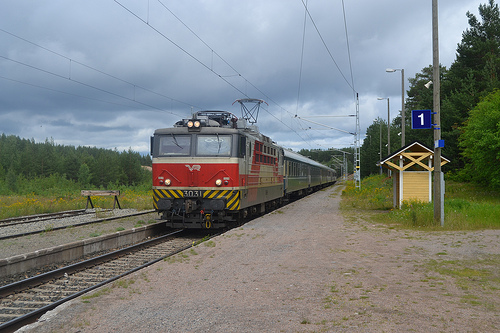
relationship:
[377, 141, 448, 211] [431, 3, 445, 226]
structure on light post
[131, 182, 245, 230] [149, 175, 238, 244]
panel on engine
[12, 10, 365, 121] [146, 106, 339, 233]
wires above train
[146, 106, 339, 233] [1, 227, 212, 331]
train on tracks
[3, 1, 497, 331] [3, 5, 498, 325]
photo taken outside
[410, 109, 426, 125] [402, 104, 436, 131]
number 1 on sign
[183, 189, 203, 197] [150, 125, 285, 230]
number on engine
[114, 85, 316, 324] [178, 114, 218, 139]
train has train headlights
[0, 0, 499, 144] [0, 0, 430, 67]
clouds in sky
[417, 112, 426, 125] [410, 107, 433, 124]
number 1 on sign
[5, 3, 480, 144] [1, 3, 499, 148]
clouds in sky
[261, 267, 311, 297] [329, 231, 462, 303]
dirt on ground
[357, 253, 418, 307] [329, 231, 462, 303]
gravel on ground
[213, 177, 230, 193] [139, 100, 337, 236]
headlight on train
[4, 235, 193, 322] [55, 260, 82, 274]
rail seen part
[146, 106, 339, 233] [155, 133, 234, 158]
train has windows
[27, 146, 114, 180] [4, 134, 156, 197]
vegetation in area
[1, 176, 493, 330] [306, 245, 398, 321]
ground has part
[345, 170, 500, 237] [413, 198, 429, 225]
grass seen part